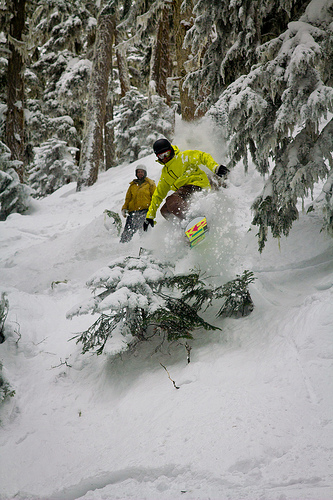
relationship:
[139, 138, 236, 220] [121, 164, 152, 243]
man watching man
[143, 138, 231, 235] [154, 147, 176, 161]
man wearing goggles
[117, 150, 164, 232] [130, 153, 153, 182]
man wearing hat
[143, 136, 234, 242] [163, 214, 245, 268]
snowboarder in air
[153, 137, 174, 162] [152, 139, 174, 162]
hat on head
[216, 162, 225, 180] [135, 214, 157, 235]
gloves on hand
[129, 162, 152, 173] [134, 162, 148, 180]
hat on head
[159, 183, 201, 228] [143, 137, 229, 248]
pants on snowboarder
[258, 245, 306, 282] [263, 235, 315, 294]
snow covers ground